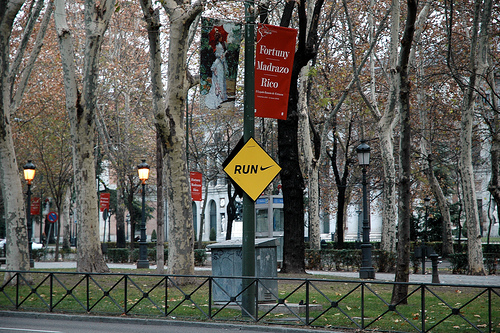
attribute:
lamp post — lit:
[135, 157, 149, 268]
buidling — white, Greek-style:
[87, 73, 384, 267]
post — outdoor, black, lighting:
[130, 165, 157, 265]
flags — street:
[194, 15, 289, 118]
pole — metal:
[235, 4, 265, 324]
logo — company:
[257, 162, 274, 171]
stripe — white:
[0, 326, 65, 331]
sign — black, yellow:
[224, 138, 283, 202]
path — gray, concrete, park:
[309, 265, 492, 284]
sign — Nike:
[189, 142, 288, 202]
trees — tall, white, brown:
[1, 2, 497, 284]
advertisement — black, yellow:
[221, 137, 282, 202]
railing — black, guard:
[0, 268, 500, 331]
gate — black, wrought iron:
[0, 257, 497, 329]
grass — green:
[3, 271, 498, 329]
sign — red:
[253, 25, 296, 121]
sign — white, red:
[254, 26, 298, 116]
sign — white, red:
[197, 15, 242, 112]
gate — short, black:
[207, 276, 310, 325]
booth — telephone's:
[257, 197, 282, 236]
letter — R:
[232, 164, 242, 174]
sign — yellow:
[224, 132, 284, 201]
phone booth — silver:
[250, 193, 305, 258]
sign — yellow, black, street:
[207, 126, 290, 201]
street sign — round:
[44, 209, 60, 223]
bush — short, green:
[399, 238, 449, 265]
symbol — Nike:
[259, 162, 277, 172]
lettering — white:
[255, 60, 291, 74]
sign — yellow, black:
[215, 128, 287, 209]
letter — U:
[240, 160, 249, 176]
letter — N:
[251, 162, 258, 174]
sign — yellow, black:
[211, 130, 289, 210]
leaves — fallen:
[16, 271, 497, 329]